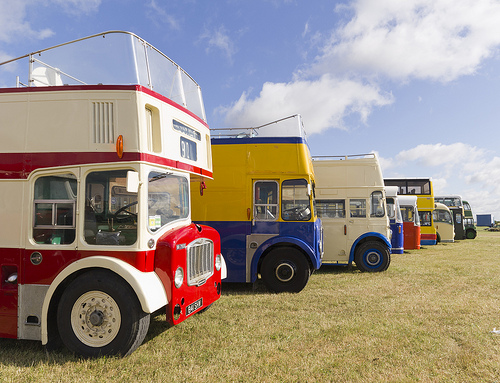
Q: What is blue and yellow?
A: Truck.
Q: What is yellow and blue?
A: RV.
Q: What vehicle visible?
A: RV.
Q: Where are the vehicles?
A: Grass.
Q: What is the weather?
A: Sunny and cloudy.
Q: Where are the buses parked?
A: On the grass.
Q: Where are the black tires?
A: On all the buses.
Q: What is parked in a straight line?
A: The buses.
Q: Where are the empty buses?
A: Parked on the grass.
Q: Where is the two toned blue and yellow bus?
A: Right next to the red and white bus.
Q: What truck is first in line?
A: The red and white one.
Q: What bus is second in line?
A: The yellow and blue one.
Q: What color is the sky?
A: Blue.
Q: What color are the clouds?
A: White.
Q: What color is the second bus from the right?
A: Blue and yellow.